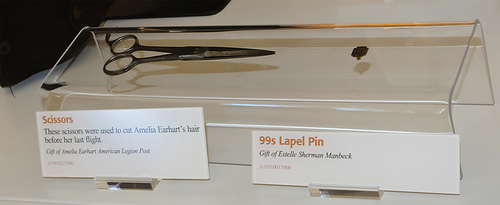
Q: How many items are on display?
A: Two.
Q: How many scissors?
A: One.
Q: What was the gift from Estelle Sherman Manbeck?
A: 99s Lapel Pin.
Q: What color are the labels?
A: White.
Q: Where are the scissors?
A: On the Left.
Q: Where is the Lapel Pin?
A: On the right.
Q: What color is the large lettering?
A: Orange.